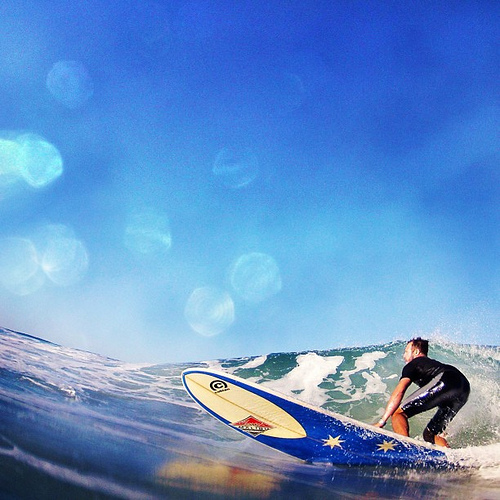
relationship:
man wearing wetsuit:
[374, 337, 473, 451] [401, 356, 470, 442]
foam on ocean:
[257, 349, 402, 416] [3, 323, 499, 499]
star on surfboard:
[322, 433, 350, 451] [180, 366, 454, 468]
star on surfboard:
[375, 437, 400, 455] [180, 366, 454, 468]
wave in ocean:
[112, 340, 499, 478] [3, 323, 499, 499]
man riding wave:
[374, 337, 473, 451] [112, 340, 499, 478]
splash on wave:
[397, 313, 488, 346] [112, 340, 499, 478]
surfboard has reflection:
[180, 366, 454, 468] [0, 375, 460, 499]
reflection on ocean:
[0, 375, 460, 499] [3, 323, 499, 499]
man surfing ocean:
[374, 337, 473, 451] [3, 323, 499, 499]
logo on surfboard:
[210, 377, 229, 395] [180, 366, 454, 468]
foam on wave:
[257, 349, 402, 416] [112, 340, 499, 478]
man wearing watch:
[374, 337, 473, 451] [378, 415, 388, 423]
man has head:
[374, 337, 473, 451] [403, 335, 429, 364]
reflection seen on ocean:
[0, 375, 460, 499] [3, 323, 499, 499]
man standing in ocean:
[374, 337, 473, 451] [3, 323, 499, 499]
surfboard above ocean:
[180, 366, 454, 468] [3, 323, 499, 499]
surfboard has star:
[180, 366, 454, 468] [322, 433, 350, 451]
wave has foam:
[112, 340, 499, 478] [257, 349, 402, 416]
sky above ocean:
[1, 1, 495, 365] [3, 323, 499, 499]